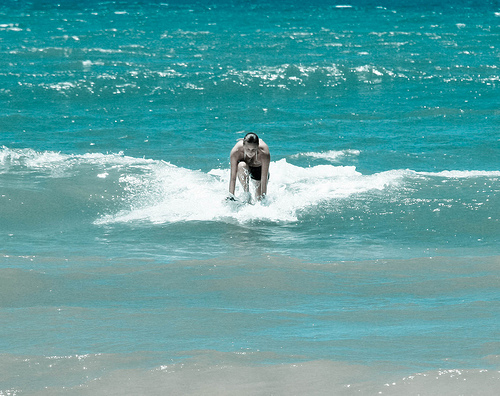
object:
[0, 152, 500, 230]
wave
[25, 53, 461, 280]
water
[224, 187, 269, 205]
hands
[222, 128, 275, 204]
girl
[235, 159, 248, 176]
knee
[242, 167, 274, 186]
pants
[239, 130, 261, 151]
hair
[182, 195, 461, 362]
ocean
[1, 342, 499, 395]
beach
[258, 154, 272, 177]
bicep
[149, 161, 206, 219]
splash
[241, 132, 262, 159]
face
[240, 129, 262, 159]
head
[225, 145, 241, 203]
arm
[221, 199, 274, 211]
surfboard